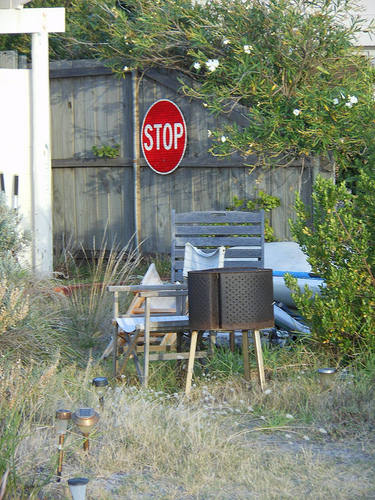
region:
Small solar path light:
[44, 405, 72, 487]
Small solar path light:
[71, 402, 110, 465]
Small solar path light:
[91, 371, 112, 423]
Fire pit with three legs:
[170, 255, 284, 419]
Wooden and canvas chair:
[100, 236, 223, 399]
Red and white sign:
[131, 90, 191, 183]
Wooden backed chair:
[162, 203, 272, 287]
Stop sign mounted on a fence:
[48, 57, 325, 208]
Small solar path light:
[65, 467, 96, 498]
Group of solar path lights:
[35, 365, 121, 498]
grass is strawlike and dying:
[126, 393, 359, 496]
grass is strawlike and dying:
[150, 435, 276, 482]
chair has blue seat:
[107, 285, 199, 397]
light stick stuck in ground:
[58, 400, 112, 470]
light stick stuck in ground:
[34, 398, 74, 478]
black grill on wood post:
[177, 258, 297, 411]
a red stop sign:
[142, 99, 190, 174]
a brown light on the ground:
[54, 410, 69, 475]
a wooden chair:
[107, 208, 262, 386]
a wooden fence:
[37, 56, 369, 277]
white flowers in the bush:
[204, 53, 220, 72]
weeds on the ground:
[108, 390, 374, 495]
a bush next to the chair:
[290, 176, 374, 367]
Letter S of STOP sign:
[142, 122, 153, 152]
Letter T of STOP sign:
[151, 122, 162, 150]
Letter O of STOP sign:
[160, 123, 172, 149]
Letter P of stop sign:
[171, 121, 183, 150]